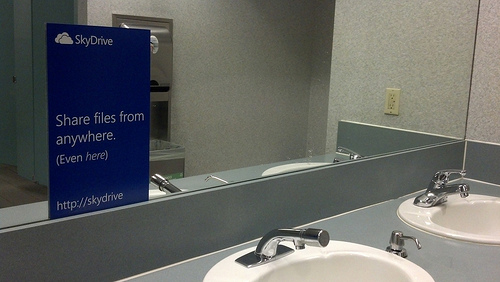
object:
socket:
[382, 87, 403, 118]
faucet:
[233, 227, 331, 270]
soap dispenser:
[384, 230, 422, 257]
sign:
[45, 21, 152, 219]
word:
[54, 112, 92, 128]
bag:
[148, 136, 187, 160]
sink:
[202, 235, 434, 282]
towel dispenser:
[116, 23, 174, 92]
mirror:
[0, 0, 480, 230]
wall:
[464, 1, 500, 141]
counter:
[116, 176, 500, 282]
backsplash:
[0, 140, 466, 282]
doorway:
[2, 1, 14, 176]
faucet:
[149, 172, 183, 195]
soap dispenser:
[201, 173, 231, 185]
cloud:
[58, 35, 73, 45]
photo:
[0, 0, 499, 281]